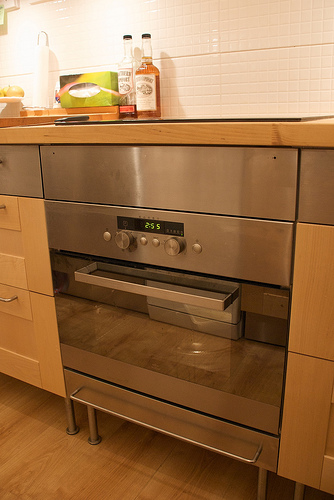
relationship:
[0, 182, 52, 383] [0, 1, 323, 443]
drawers in kitchen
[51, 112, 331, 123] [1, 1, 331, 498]
cooktop in kitchen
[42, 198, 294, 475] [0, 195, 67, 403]
oven between cupboards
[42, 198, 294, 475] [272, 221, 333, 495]
oven between cupboards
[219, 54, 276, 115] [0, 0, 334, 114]
tile on wall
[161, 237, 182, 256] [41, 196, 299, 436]
control for oven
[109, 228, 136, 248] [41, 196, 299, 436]
control for oven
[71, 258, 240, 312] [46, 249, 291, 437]
handle for oven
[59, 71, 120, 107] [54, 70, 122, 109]
box of tissue